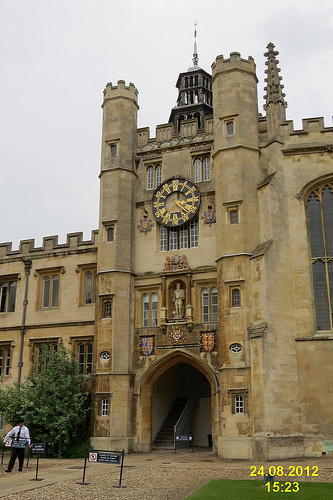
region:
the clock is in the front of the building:
[130, 165, 217, 239]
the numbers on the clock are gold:
[107, 166, 205, 219]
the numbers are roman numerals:
[138, 171, 208, 229]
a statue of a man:
[156, 269, 191, 333]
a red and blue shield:
[119, 322, 223, 363]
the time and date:
[235, 450, 326, 495]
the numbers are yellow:
[238, 451, 329, 498]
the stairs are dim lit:
[153, 378, 189, 457]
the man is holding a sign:
[0, 410, 28, 463]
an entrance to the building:
[109, 341, 226, 464]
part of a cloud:
[103, 15, 133, 58]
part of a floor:
[138, 449, 159, 484]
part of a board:
[115, 447, 121, 461]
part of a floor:
[227, 464, 254, 483]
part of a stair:
[161, 402, 200, 453]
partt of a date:
[260, 455, 287, 480]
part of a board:
[83, 431, 112, 477]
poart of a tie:
[5, 430, 30, 451]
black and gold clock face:
[150, 176, 201, 230]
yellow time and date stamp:
[248, 461, 319, 493]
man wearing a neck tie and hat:
[0, 415, 33, 470]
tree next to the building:
[0, 338, 96, 456]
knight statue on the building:
[169, 279, 186, 318]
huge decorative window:
[295, 170, 332, 340]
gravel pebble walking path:
[0, 443, 332, 498]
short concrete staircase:
[151, 382, 199, 448]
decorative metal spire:
[185, 18, 203, 70]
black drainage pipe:
[17, 256, 32, 390]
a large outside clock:
[129, 114, 223, 239]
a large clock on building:
[83, 118, 302, 343]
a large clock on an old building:
[55, 82, 331, 355]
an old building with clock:
[68, 79, 330, 416]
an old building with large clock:
[72, 61, 331, 394]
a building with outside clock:
[91, 67, 310, 374]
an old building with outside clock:
[58, 78, 332, 365]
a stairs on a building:
[137, 362, 207, 473]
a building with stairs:
[116, 350, 226, 473]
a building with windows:
[51, 31, 277, 469]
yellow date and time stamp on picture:
[247, 455, 321, 496]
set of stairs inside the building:
[154, 389, 192, 451]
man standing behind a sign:
[1, 418, 31, 478]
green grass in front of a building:
[199, 477, 254, 496]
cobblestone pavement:
[134, 467, 180, 496]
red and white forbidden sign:
[87, 450, 96, 462]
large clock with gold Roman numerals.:
[145, 170, 206, 231]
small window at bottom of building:
[227, 387, 246, 415]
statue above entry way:
[163, 270, 192, 324]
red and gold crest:
[197, 329, 218, 354]